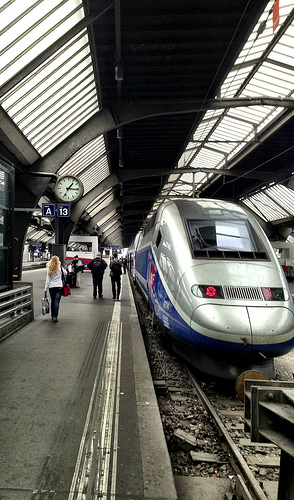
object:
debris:
[172, 402, 213, 455]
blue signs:
[41, 203, 70, 218]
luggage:
[42, 293, 50, 315]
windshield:
[173, 200, 270, 263]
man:
[109, 253, 122, 299]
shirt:
[109, 257, 123, 277]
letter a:
[46, 208, 52, 216]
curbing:
[69, 299, 178, 500]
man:
[87, 254, 108, 299]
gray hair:
[96, 252, 101, 256]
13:
[59, 208, 68, 216]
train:
[125, 196, 294, 358]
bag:
[61, 266, 71, 297]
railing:
[0, 284, 32, 341]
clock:
[54, 174, 84, 203]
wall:
[0, 5, 117, 322]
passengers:
[44, 255, 68, 323]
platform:
[1, 257, 179, 498]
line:
[67, 302, 123, 499]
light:
[263, 289, 272, 298]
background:
[43, 204, 55, 217]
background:
[57, 205, 70, 217]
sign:
[42, 203, 55, 217]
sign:
[57, 204, 70, 217]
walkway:
[1, 258, 178, 500]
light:
[206, 286, 216, 297]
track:
[180, 360, 294, 500]